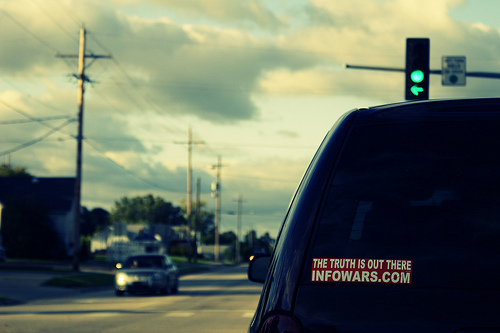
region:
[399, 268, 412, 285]
white letter on a red bumper sticker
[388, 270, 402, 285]
white letter on a red bumper sticker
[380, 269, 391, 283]
white letter on a red bumper sticker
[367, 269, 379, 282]
white letter on a red bumper sticker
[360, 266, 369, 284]
white letter on a red bumper sticker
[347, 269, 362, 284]
white letter on a red bumper sticker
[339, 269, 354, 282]
white letter on a red bumper sticker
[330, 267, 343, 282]
white letter on a red bumper sticker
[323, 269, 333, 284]
white letter on a red bumper sticker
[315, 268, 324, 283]
white letter on a red bumper sticker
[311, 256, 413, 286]
Sticker on the back of a car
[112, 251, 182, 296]
Front end of a car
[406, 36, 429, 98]
Traffic light showing green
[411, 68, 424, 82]
Green light on a traffic signal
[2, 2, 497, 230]
Fluffy clouds in the sky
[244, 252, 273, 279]
Side mirror on a car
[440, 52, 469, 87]
Sign beside a traffic signal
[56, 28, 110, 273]
A tall utility pole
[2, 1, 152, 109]
Overhead power lines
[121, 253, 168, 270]
Front windshield on a car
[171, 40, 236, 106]
a cloud in the sky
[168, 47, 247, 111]
the cloud is white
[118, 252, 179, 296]
a car in the street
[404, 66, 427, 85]
a green light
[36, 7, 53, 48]
electrical lines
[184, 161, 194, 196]
a pole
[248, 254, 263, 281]
mirror on the car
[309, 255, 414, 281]
a sticker on the car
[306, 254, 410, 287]
sticker is red and white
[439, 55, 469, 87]
a sign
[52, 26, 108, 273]
this is a post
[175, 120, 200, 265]
this is a post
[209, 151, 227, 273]
this is a post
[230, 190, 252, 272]
this is a post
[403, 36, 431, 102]
this is a traffic light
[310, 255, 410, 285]
this is a sentence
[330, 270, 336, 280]
this is a letter in a sentence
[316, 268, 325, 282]
this is a letter in a sentence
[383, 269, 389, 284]
this is a letter in a sentence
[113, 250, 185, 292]
this is a car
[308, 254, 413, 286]
A sticker on a window.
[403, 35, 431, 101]
A traffic light on green.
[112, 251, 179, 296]
A car on the street.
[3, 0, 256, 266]
Power lines and poles.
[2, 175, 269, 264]
Houses on a street.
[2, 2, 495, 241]
Clouds in the sky.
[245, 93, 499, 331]
Part of an SUV.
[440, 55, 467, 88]
A sign on a pole.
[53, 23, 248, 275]
Power poles line the street.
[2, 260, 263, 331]
A paved road.